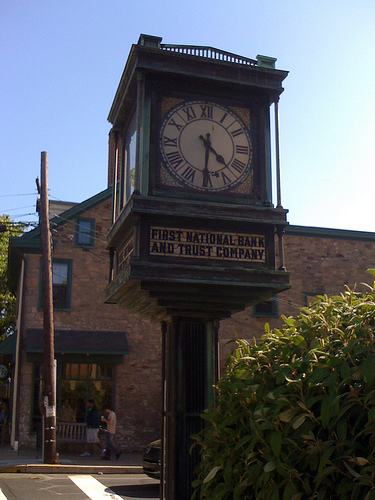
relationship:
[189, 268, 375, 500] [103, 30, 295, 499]
bush beside clock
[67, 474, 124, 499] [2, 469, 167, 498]
line on road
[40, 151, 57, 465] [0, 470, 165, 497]
pole on street corner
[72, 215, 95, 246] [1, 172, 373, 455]
window in building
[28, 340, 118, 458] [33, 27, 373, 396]
window on building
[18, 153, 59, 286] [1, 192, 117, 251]
pole supporting wires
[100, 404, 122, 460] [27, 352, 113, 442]
man walking in front of window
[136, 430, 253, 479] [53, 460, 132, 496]
car behind line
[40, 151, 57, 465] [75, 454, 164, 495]
pole on sidewalk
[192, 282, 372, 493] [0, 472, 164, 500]
bush on road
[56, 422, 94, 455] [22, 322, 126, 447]
bench beneath window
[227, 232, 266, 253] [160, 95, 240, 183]
bank sponsoring clock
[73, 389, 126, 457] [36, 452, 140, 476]
pedestrians on sidewalk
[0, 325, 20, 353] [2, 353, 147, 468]
canopy over storefront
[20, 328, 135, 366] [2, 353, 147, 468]
canopy over storefront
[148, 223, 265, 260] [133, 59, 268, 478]
signs posted on light post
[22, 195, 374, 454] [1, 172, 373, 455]
brick wall on building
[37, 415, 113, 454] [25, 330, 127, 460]
bench in front of window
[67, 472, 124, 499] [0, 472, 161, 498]
line on road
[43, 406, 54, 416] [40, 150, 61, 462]
paper attached to pole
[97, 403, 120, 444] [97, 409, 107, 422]
man carrying drink